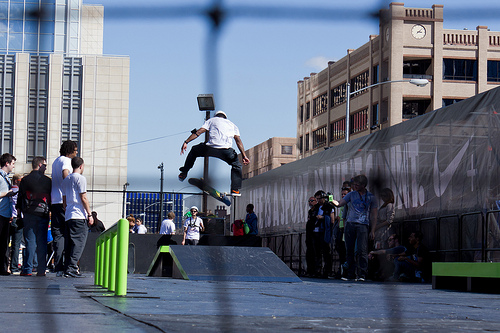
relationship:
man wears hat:
[173, 110, 253, 198] [211, 108, 229, 119]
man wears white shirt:
[173, 110, 253, 198] [197, 119, 243, 149]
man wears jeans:
[173, 110, 253, 198] [178, 140, 249, 189]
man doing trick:
[173, 110, 253, 198] [145, 107, 264, 222]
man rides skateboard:
[173, 110, 253, 198] [186, 175, 234, 207]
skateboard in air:
[186, 175, 234, 207] [146, 143, 312, 251]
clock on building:
[407, 22, 429, 46] [294, 2, 498, 160]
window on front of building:
[1, 2, 69, 61] [2, 2, 137, 210]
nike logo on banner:
[422, 126, 478, 217] [235, 84, 496, 241]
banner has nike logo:
[235, 84, 496, 241] [422, 126, 478, 217]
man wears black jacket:
[12, 153, 59, 279] [13, 170, 57, 218]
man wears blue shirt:
[240, 203, 270, 244] [242, 211, 263, 236]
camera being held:
[325, 192, 336, 205] [324, 192, 343, 210]